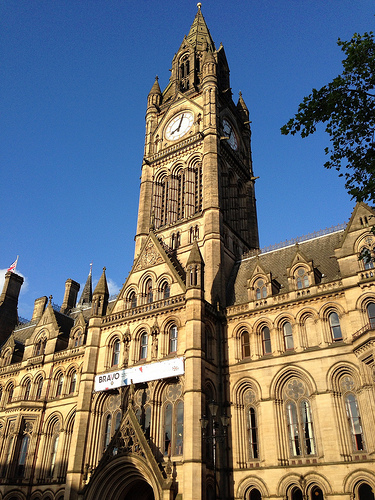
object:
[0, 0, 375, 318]
sky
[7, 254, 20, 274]
flag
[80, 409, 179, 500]
entrance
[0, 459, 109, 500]
shadows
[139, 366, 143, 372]
triangles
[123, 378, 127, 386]
triangles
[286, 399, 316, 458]
curtains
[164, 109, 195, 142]
clock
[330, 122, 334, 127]
ground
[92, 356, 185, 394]
board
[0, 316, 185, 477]
windows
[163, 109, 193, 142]
face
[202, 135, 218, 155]
stone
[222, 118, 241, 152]
clock face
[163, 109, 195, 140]
field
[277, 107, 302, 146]
ground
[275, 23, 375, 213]
tree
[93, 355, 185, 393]
sign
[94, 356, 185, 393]
banner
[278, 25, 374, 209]
leaves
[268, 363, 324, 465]
window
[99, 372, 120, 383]
letters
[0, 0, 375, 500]
building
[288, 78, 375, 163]
branches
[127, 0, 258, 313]
tower